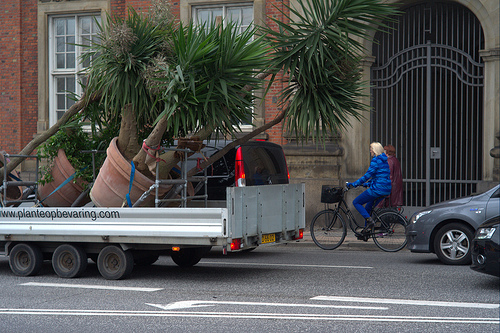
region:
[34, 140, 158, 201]
the big flower pots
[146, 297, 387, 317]
an arrow on ground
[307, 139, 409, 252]
a lady on the bike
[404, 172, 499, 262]
a grey car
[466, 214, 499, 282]
front end of black car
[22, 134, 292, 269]
a black suv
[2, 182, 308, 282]
a service truck for deliveries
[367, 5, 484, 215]
a gated entrance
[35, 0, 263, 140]
windows on building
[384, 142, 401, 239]
a lady with red hair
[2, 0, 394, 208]
really big potted plants being transported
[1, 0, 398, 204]
several potted palm trees en route to somewhere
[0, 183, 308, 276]
potted trees are on a flatbed truck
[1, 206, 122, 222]
name of the truck's owner on the side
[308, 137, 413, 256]
a bicyclist is part of the traffic flow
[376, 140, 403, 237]
a pedestrian is walking down the sidewalk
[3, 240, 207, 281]
transport truck has six rear wheels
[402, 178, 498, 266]
gray car following the truck in the next lane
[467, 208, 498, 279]
black car is directly behind the tree truck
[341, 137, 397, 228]
bicyclist is wearing bright blue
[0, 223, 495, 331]
The road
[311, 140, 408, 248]
A woman riding a bicycle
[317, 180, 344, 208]
A basket on the front of a bicycle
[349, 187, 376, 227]
A pair of blue pants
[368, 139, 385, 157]
A woman with blonde hair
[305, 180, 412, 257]
A bicycle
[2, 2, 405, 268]
A flatbed with large potted trees on it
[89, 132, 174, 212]
A large brown flowerpot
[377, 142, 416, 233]
A person walking on the sidewalk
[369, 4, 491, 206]
A metal gate doorway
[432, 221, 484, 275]
a tire on a car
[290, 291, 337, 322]
white line on the street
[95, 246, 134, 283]
a wheel on a trailer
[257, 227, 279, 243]
a tag on a truck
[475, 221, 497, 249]
headlight on a car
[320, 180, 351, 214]
a bag on a bike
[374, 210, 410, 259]
tire on a bike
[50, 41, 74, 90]
a window on a building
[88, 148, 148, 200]
a big brown flower pot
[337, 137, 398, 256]
a person riding a bike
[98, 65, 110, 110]
green stem on plant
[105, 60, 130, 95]
green stem on plant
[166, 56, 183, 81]
green stem on plant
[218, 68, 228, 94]
green stem on plant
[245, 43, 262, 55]
green stem on plant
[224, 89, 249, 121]
green stem on plant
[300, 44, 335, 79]
green stem on plant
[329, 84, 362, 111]
green stem on plant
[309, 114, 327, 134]
green stem on plant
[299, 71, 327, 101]
green stem on plant